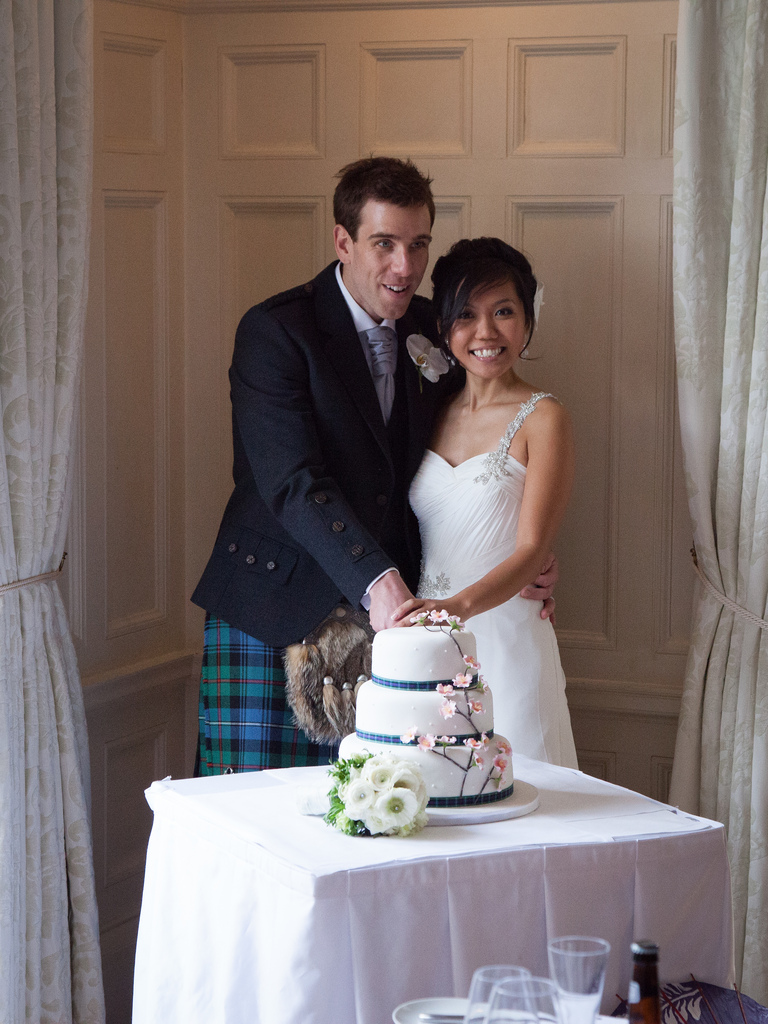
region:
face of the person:
[325, 165, 502, 331]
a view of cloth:
[171, 838, 417, 1004]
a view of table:
[203, 852, 362, 961]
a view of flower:
[349, 777, 440, 849]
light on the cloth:
[202, 884, 328, 949]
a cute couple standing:
[224, 137, 602, 604]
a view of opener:
[618, 928, 660, 972]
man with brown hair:
[327, 147, 441, 284]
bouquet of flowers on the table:
[317, 745, 425, 854]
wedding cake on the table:
[350, 609, 531, 830]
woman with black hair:
[426, 229, 537, 351]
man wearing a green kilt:
[192, 601, 336, 780]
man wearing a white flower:
[406, 328, 453, 385]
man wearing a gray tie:
[359, 318, 398, 417]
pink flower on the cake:
[424, 657, 482, 723]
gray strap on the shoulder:
[480, 382, 555, 456]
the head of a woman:
[425, 245, 536, 392]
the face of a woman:
[438, 267, 541, 396]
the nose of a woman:
[447, 306, 508, 347]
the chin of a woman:
[460, 350, 523, 393]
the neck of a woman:
[441, 346, 557, 444]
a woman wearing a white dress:
[384, 372, 607, 646]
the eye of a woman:
[476, 278, 526, 341]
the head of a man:
[324, 133, 499, 339]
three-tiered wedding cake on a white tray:
[338, 610, 542, 826]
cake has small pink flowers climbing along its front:
[335, 607, 517, 808]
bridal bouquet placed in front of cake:
[320, 607, 516, 838]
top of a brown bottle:
[624, 941, 661, 1023]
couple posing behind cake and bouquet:
[189, 154, 580, 839]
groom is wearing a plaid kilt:
[192, 155, 560, 778]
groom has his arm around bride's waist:
[189, 154, 580, 779]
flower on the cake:
[385, 792, 423, 827]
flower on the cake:
[484, 754, 525, 779]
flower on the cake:
[451, 718, 492, 776]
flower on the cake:
[396, 730, 432, 754]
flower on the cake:
[396, 712, 432, 764]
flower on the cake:
[445, 683, 470, 723]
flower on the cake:
[423, 668, 442, 695]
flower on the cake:
[465, 661, 481, 704]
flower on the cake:
[454, 690, 484, 722]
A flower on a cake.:
[415, 732, 436, 750]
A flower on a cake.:
[398, 725, 421, 743]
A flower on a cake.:
[438, 733, 462, 742]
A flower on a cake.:
[465, 739, 485, 745]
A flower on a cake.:
[478, 731, 488, 745]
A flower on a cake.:
[472, 748, 484, 767]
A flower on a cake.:
[490, 754, 506, 766]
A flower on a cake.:
[478, 735, 492, 752]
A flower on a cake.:
[440, 701, 458, 717]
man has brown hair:
[309, 140, 437, 289]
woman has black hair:
[425, 217, 522, 340]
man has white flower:
[395, 318, 487, 400]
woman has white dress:
[412, 375, 621, 786]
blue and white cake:
[362, 616, 552, 838]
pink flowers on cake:
[414, 611, 507, 821]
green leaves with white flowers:
[297, 754, 454, 852]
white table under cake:
[210, 759, 727, 969]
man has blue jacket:
[208, 267, 453, 622]